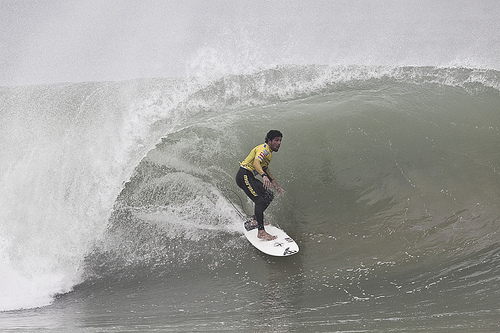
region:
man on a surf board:
[228, 124, 309, 264]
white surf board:
[241, 211, 306, 263]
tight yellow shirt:
[227, 137, 289, 178]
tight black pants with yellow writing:
[227, 161, 282, 232]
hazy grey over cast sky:
[2, 0, 496, 87]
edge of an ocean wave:
[2, 59, 499, 111]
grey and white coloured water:
[1, 63, 498, 331]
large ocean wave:
[4, 56, 499, 316]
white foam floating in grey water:
[131, 220, 498, 331]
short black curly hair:
[262, 126, 287, 145]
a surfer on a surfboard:
[231, 120, 291, 245]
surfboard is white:
[233, 211, 310, 261]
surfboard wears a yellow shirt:
[231, 116, 291, 241]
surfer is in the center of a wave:
[17, 44, 498, 314]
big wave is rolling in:
[0, 61, 496, 316]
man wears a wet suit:
[231, 116, 296, 245]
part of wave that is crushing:
[0, 59, 208, 330]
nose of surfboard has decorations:
[270, 233, 307, 262]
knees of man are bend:
[233, 185, 288, 210]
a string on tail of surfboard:
[210, 188, 254, 228]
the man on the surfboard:
[213, 121, 296, 243]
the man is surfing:
[212, 125, 319, 275]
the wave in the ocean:
[17, 66, 453, 312]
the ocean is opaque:
[331, 125, 471, 305]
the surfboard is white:
[235, 210, 295, 261]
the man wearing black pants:
[225, 165, 280, 230]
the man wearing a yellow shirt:
[231, 140, 276, 170]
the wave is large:
[20, 67, 257, 306]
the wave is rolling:
[12, 70, 387, 310]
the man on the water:
[225, 122, 315, 277]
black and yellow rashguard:
[243, 136, 273, 218]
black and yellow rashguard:
[234, 126, 288, 223]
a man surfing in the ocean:
[234, 125, 301, 261]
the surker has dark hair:
[264, 127, 284, 156]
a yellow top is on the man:
[239, 141, 273, 173]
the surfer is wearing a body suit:
[237, 148, 272, 229]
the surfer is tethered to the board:
[223, 186, 299, 257]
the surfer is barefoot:
[253, 224, 281, 244]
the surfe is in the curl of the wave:
[97, 53, 354, 295]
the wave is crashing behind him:
[8, 46, 302, 309]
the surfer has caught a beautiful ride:
[159, 50, 356, 290]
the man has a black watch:
[256, 168, 273, 185]